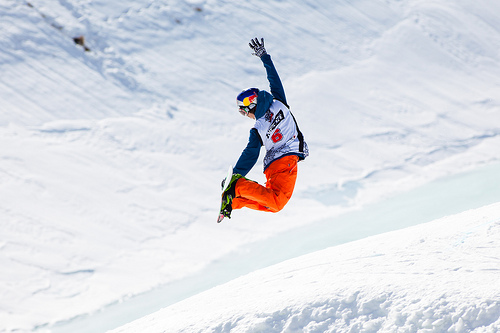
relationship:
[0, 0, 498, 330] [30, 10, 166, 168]
snow on hill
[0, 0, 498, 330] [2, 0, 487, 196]
snow on hill side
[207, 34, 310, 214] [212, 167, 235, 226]
man grabbing snow board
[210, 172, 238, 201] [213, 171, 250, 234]
hand grabbing snow board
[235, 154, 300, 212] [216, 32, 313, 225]
pants on man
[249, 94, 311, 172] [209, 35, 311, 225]
top on person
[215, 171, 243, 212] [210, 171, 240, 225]
shoes on board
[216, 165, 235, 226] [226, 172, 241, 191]
snow board on feet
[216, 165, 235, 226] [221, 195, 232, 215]
snow board on feet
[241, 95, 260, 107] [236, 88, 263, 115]
logo on helmet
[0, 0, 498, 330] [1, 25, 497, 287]
snow covering mountain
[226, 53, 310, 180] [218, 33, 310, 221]
coat on snowboarder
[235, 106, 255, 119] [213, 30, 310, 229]
goggles on snowboarder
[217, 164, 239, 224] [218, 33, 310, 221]
snowboard on snowboarder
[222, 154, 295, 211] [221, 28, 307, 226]
orange pants on person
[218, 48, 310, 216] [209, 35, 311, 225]
jacket on person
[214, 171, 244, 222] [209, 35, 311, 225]
shoes on person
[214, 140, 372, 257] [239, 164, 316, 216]
pants on legs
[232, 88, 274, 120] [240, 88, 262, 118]
helmet on head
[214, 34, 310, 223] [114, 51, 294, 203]
man in air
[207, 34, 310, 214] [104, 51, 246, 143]
man snow boarding in air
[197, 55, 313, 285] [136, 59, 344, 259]
snowboarder in air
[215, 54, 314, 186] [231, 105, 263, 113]
person wearing eyeglass